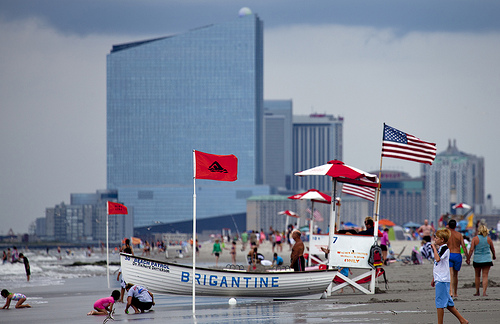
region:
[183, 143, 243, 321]
a red and black flag in the sand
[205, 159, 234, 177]
black logo on the red flag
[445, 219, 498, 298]
woman in blue tank holding hands with man in blue shorts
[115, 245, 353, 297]
white and blue boat on the sand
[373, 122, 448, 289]
red, white, and blue USA flag in the sand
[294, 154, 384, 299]
red and white umbrella in the sand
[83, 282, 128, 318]
girl wearing pink on the sand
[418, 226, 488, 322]
boy with blonde hair standing on the sand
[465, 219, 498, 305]
woman with blonde hair wearing a blue tank top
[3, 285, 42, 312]
girl in bathing suit playing in the sand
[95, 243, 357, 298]
A WHITE BOAT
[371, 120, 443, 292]
THE AMERICAN FLAG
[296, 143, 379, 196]
A RED AND WHITE UMBRELLA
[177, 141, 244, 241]
A RED FLAG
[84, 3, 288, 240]
A HIGH RISE BUILDING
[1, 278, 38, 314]
A LITTLE GIRL PLAYING ON THE SAND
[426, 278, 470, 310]
A PAIR OF BLUE SHORTS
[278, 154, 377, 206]
TWO RED AND WHITE UMBRELLAS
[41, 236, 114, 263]
PEOPLE PLAYING IN THE WATER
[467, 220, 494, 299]
A WOMAN WALKING AWAY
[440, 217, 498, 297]
a tan couple holding hands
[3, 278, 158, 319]
children playing on the beach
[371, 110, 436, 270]
american flag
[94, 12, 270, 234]
very large building with lots of windows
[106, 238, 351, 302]
white boat on the shore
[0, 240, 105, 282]
people in the water at the beach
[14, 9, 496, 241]
large city with many different buildings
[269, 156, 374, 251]
three red and white umbrellas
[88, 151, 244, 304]
two red flags on white poles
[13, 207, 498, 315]
many people on the beach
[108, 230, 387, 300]
Boat on the beach.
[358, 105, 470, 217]
American flag on the beach.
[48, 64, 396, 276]
City skyline on the beach.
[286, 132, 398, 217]
Umbrella on the beach.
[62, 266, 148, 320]
Children playing on the beach.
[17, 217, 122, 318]
Ocean waves on the beach.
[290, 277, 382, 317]
Sand on the beach.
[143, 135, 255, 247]
Red flag blowing in the wind.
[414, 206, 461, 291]
Boy on the beach.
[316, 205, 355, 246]
Number seven on the sign.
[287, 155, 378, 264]
red and white beach umbrellas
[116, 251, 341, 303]
a blue and white beach patrol boat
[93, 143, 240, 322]
red flags on white poles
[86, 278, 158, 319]
children playing on the beach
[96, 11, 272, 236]
a skyscraper neat the beach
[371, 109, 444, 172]
an american flag on a pole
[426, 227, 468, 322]
a young man on the beach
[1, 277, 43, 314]
a small girl playing in the sand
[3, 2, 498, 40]
gray clouds in the sky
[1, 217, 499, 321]
people on the busy beach